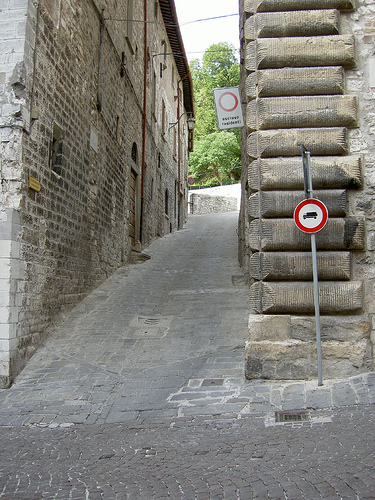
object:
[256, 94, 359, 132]
brick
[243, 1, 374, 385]
wall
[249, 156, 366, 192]
brick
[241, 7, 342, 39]
brick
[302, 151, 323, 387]
pole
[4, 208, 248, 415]
road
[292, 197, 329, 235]
sign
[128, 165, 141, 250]
door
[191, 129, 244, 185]
tree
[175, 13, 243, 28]
line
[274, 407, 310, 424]
drain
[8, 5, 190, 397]
wall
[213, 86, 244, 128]
sign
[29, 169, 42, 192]
sign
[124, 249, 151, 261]
steps